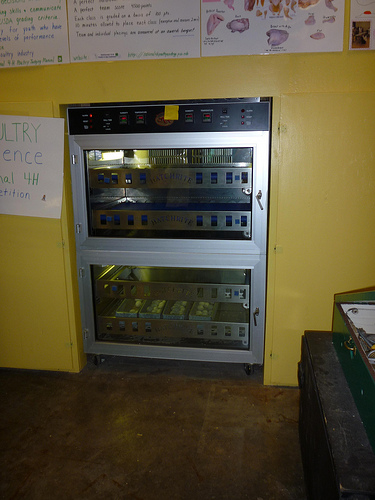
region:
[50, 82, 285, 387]
The oven in the wall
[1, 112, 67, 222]
The sign on the wall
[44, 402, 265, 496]
The floor is made of concrete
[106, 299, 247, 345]
The bottom shelf has bread in it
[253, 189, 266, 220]
The handle to the door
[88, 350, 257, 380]
The wheels to the oven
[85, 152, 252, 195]
The top shelf to the oven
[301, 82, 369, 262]
The color of the wall is yellow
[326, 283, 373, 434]
The green box in the kitchen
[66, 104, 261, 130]
The temperature controls to the oven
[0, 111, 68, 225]
handwritten sign on the wall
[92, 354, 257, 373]
wheels on the bottom of the oven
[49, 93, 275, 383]
oven pushed into a crevice in the wall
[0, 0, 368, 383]
yellow paint on the wall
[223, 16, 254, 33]
picture on the sign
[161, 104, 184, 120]
yellow sticky note on the oven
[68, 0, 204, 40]
black writing on a white background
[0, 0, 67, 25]
green writing on a white background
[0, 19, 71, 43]
blue writing on a white background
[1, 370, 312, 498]
dark tile on the floor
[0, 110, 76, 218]
corner of a white sign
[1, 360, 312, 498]
a dirty brown floor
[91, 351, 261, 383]
wheels under the oven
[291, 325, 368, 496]
large black box on the ground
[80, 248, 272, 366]
bottom oven window with things inside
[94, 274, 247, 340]
racks inside the bottom oven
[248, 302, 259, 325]
handle of the oven window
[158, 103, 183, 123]
yellow note on the oven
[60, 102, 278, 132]
controls and lights on the oven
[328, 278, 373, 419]
green box on the side of the ovens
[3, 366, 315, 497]
old brown floor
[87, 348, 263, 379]
wheels underneath the oven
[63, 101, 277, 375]
a double stacked oven system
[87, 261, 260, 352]
oven window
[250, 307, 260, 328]
silver handle on the oven door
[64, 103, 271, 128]
buttons and controls on the oven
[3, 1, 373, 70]
signs above the ovens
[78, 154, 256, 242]
blue objects in the metal oven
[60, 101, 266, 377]
a commercial refrigerator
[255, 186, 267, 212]
handle of a refrigerator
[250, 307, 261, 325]
handle of a refrigerator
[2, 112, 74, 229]
a white board on a wall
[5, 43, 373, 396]
the wall is yellow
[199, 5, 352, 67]
a white board on wall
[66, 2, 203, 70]
a white board on wall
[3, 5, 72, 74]
a white board on wall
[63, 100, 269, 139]
command buttons of refrigerator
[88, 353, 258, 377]
front wheels of refrigerator